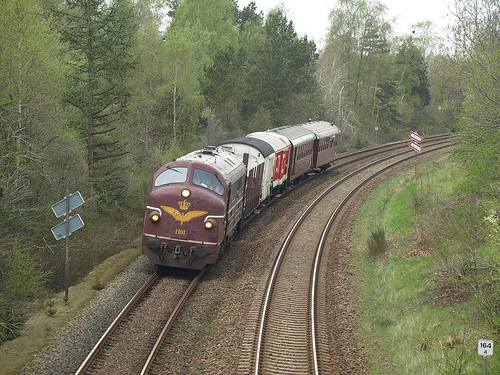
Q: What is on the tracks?
A: A train.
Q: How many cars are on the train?
A: Six.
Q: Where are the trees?
A: On both sides of the train track.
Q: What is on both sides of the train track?
A: Trees.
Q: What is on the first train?
A: A crown and bird.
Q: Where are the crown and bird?
A: On the front of the first train.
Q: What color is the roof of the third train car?
A: Black.